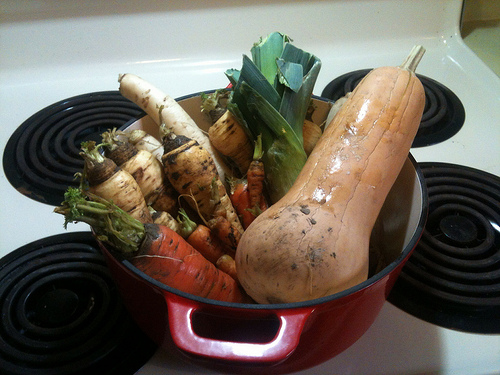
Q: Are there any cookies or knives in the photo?
A: No, there are no knives or cookies.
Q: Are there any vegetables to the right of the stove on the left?
A: Yes, there is a vegetable to the right of the stove.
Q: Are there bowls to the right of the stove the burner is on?
A: No, there is a vegetable to the right of the stove.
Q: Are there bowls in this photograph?
A: No, there are no bowls.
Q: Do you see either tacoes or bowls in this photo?
A: No, there are no bowls or tacoes.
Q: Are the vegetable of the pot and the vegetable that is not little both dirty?
A: Yes, both the vegetable and the vegetable are dirty.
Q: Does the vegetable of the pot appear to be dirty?
A: Yes, the vegetable is dirty.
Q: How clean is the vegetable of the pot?
A: The vegetable is dirty.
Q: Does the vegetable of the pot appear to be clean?
A: No, the vegetable is dirty.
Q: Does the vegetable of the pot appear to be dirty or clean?
A: The vegetable is dirty.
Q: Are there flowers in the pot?
A: No, there is a vegetable in the pot.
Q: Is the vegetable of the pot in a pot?
A: Yes, the vegetable is in a pot.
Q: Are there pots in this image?
A: Yes, there is a pot.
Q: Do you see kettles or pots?
A: Yes, there is a pot.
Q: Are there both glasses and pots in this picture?
A: No, there is a pot but no glasses.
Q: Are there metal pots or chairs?
A: Yes, there is a metal pot.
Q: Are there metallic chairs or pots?
A: Yes, there is a metal pot.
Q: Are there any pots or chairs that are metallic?
A: Yes, the pot is metallic.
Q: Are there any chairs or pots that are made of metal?
A: Yes, the pot is made of metal.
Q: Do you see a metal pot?
A: Yes, there is a pot that is made of metal.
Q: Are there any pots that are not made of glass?
A: Yes, there is a pot that is made of metal.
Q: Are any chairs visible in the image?
A: No, there are no chairs.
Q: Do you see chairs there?
A: No, there are no chairs.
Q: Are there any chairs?
A: No, there are no chairs.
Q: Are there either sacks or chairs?
A: No, there are no chairs or sacks.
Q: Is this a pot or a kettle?
A: This is a pot.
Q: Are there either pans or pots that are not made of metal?
A: No, there is a pot but it is made of metal.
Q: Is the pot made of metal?
A: Yes, the pot is made of metal.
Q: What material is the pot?
A: The pot is made of metal.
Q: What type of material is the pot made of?
A: The pot is made of metal.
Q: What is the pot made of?
A: The pot is made of metal.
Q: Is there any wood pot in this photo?
A: No, there is a pot but it is made of metal.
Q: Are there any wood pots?
A: No, there is a pot but it is made of metal.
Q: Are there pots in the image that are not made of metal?
A: No, there is a pot but it is made of metal.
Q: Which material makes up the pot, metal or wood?
A: The pot is made of metal.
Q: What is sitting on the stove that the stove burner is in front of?
A: The pot is sitting on the stove.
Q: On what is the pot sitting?
A: The pot is sitting on the stove.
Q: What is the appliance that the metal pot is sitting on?
A: The appliance is a stove.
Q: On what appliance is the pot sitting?
A: The pot is sitting on the stove.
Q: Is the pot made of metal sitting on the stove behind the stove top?
A: Yes, the pot is sitting on the stove.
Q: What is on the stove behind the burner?
A: The pot is on the stove.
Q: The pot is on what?
A: The pot is on the stove.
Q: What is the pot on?
A: The pot is on the stove.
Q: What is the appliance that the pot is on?
A: The appliance is a stove.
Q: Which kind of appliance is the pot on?
A: The pot is on the stove.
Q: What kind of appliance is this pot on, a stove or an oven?
A: The pot is on a stove.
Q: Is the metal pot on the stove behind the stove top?
A: Yes, the pot is on the stove.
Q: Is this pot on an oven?
A: No, the pot is on the stove.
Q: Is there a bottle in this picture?
A: No, there are no bottles.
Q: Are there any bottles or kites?
A: No, there are no bottles or kites.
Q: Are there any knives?
A: No, there are no knives.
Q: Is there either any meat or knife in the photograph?
A: No, there are no knives or meat.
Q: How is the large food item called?
A: The food item is a vegetable.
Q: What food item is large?
A: The food item is a vegetable.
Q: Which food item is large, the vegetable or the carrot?
A: The vegetable is large.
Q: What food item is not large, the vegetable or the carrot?
A: The carrot is not large.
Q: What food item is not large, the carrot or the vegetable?
A: The carrot is not large.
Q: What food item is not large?
A: The food item is a carrot.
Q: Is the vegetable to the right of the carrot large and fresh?
A: Yes, the vegetable is large and fresh.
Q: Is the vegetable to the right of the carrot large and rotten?
A: No, the vegetable is large but fresh.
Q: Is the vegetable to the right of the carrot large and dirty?
A: Yes, the vegetable is large and dirty.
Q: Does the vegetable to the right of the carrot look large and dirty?
A: Yes, the vegetable is large and dirty.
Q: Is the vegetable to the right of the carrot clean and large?
A: No, the vegetable is large but dirty.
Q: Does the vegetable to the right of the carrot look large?
A: Yes, the vegetable is large.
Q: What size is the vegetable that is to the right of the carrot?
A: The vegetable is large.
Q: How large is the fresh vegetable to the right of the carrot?
A: The vegetable is large.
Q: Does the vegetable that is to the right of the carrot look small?
A: No, the vegetable is large.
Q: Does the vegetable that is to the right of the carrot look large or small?
A: The vegetable is large.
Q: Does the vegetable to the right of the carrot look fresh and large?
A: Yes, the vegetable is fresh and large.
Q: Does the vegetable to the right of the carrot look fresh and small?
A: No, the vegetable is fresh but large.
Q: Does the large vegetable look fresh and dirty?
A: Yes, the vegetable is fresh and dirty.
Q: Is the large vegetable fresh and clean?
A: No, the vegetable is fresh but dirty.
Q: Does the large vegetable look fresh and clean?
A: No, the vegetable is fresh but dirty.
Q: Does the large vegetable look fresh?
A: Yes, the vegetable is fresh.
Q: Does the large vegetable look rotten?
A: No, the vegetable is fresh.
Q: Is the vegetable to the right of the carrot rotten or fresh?
A: The vegetable is fresh.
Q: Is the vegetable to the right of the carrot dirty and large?
A: Yes, the vegetable is dirty and large.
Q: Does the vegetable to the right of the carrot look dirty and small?
A: No, the vegetable is dirty but large.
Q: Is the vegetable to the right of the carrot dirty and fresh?
A: Yes, the vegetable is dirty and fresh.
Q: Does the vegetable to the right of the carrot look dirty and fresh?
A: Yes, the vegetable is dirty and fresh.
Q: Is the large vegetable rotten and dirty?
A: No, the vegetable is dirty but fresh.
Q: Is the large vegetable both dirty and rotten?
A: No, the vegetable is dirty but fresh.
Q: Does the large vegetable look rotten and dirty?
A: No, the vegetable is dirty but fresh.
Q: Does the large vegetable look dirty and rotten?
A: No, the vegetable is dirty but fresh.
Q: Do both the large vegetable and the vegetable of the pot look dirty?
A: Yes, both the vegetable and the vegetable are dirty.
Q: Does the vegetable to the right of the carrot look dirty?
A: Yes, the vegetable is dirty.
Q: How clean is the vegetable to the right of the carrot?
A: The vegetable is dirty.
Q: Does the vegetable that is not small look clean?
A: No, the vegetable is dirty.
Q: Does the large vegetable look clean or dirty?
A: The vegetable is dirty.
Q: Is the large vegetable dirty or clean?
A: The vegetable is dirty.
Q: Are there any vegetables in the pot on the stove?
A: Yes, there is a vegetable in the pot.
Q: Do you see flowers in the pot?
A: No, there is a vegetable in the pot.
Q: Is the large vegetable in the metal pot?
A: Yes, the vegetable is in the pot.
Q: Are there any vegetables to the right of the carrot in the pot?
A: Yes, there is a vegetable to the right of the carrot.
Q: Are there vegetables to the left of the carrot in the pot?
A: No, the vegetable is to the right of the carrot.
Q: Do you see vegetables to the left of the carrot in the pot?
A: No, the vegetable is to the right of the carrot.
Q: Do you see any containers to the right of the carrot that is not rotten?
A: No, there is a vegetable to the right of the carrot.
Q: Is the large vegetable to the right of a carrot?
A: Yes, the vegetable is to the right of a carrot.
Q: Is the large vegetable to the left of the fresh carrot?
A: No, the vegetable is to the right of the carrot.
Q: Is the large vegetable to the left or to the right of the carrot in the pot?
A: The vegetable is to the right of the carrot.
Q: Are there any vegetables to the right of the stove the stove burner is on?
A: Yes, there is a vegetable to the right of the stove.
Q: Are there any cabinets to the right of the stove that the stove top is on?
A: No, there is a vegetable to the right of the stove.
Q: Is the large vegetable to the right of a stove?
A: Yes, the vegetable is to the right of a stove.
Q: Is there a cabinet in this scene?
A: No, there are no cabinets.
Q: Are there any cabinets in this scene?
A: No, there are no cabinets.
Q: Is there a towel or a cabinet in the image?
A: No, there are no cabinets or towels.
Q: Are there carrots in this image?
A: Yes, there is a carrot.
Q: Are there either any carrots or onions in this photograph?
A: Yes, there is a carrot.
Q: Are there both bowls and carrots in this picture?
A: No, there is a carrot but no bowls.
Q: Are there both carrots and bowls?
A: No, there is a carrot but no bowls.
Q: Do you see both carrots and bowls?
A: No, there is a carrot but no bowls.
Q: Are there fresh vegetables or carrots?
A: Yes, there is a fresh carrot.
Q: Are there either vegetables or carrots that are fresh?
A: Yes, the carrot is fresh.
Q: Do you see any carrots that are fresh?
A: Yes, there is a fresh carrot.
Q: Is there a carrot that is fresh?
A: Yes, there is a carrot that is fresh.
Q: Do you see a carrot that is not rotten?
A: Yes, there is a fresh carrot.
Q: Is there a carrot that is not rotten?
A: Yes, there is a fresh carrot.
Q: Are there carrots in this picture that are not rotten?
A: Yes, there is a fresh carrot.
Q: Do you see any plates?
A: No, there are no plates.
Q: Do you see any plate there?
A: No, there are no plates.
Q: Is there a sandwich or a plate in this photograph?
A: No, there are no plates or sandwiches.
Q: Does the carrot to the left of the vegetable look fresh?
A: Yes, the carrot is fresh.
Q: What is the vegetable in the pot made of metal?
A: The vegetable is a carrot.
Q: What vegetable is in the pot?
A: The vegetable is a carrot.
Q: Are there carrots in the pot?
A: Yes, there is a carrot in the pot.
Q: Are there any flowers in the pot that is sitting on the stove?
A: No, there is a carrot in the pot.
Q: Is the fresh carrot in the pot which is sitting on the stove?
A: Yes, the carrot is in the pot.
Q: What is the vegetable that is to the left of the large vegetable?
A: The vegetable is a carrot.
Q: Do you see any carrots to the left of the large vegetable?
A: Yes, there is a carrot to the left of the vegetable.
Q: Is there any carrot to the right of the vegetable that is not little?
A: No, the carrot is to the left of the vegetable.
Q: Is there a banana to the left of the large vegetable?
A: No, there is a carrot to the left of the vegetable.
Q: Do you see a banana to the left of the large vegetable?
A: No, there is a carrot to the left of the vegetable.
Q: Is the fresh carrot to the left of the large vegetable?
A: Yes, the carrot is to the left of the vegetable.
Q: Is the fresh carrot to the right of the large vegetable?
A: No, the carrot is to the left of the vegetable.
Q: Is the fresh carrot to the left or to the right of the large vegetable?
A: The carrot is to the left of the vegetable.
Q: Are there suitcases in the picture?
A: No, there are no suitcases.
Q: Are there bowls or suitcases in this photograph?
A: No, there are no suitcases or bowls.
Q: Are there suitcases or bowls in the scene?
A: No, there are no suitcases or bowls.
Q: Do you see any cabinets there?
A: No, there are no cabinets.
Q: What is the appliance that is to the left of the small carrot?
A: The appliance is a stove.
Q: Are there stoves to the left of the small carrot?
A: Yes, there is a stove to the left of the carrot.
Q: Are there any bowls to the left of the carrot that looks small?
A: No, there is a stove to the left of the carrot.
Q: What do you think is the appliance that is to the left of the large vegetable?
A: The appliance is a stove.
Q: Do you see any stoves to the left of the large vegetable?
A: Yes, there is a stove to the left of the vegetable.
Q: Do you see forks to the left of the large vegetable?
A: No, there is a stove to the left of the vegetable.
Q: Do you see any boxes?
A: No, there are no boxes.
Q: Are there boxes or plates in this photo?
A: No, there are no boxes or plates.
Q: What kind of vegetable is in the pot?
A: The vegetable is an artichoke.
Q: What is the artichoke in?
A: The artichoke is in the pot.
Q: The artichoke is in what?
A: The artichoke is in the pot.